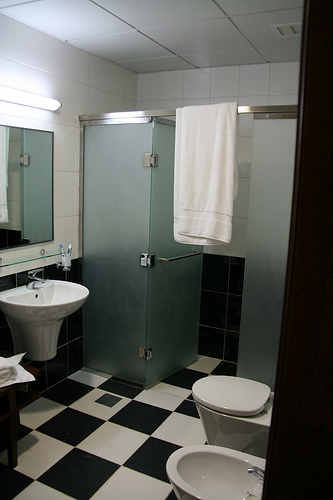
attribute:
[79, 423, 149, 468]
tile — white, large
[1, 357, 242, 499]
floor — tiled, black, white, checkered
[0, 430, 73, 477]
white tile — large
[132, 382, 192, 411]
tile — white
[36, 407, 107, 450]
black tile — large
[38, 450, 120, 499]
tile — black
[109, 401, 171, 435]
black tile — large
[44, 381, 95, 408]
tile — black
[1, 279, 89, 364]
bathroom sink — white, mounted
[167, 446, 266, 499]
bidet — white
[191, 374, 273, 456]
toilet — white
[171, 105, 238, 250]
towel — white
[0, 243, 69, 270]
shelf — glass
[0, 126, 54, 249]
mirror — hanging, framed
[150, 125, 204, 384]
shower doors — glass, foggy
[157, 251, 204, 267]
door handle — silver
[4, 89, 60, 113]
florescent light — bright